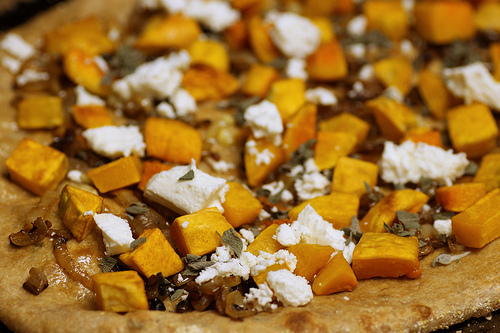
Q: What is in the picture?
A: Pizza.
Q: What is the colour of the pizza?
A: Brown.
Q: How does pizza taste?
A: Sweet.